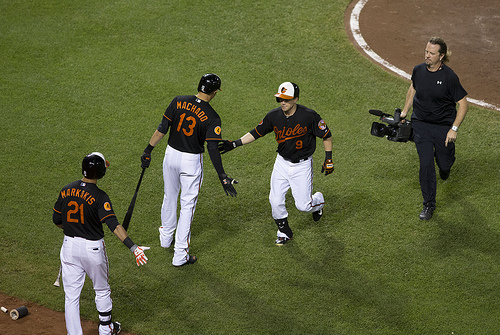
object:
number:
[177, 113, 196, 136]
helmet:
[197, 73, 222, 94]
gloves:
[206, 140, 238, 197]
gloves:
[320, 150, 334, 174]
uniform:
[52, 179, 118, 241]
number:
[294, 139, 303, 148]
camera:
[368, 108, 413, 142]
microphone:
[368, 109, 384, 116]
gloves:
[219, 138, 240, 154]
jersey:
[157, 95, 221, 154]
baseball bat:
[120, 169, 145, 231]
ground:
[318, 208, 379, 253]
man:
[140, 73, 240, 266]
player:
[217, 81, 334, 247]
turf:
[78, 51, 163, 97]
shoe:
[171, 255, 198, 268]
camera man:
[399, 38, 469, 219]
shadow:
[427, 190, 499, 257]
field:
[1, 1, 498, 333]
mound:
[384, 13, 494, 68]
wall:
[268, 153, 324, 219]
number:
[67, 200, 79, 224]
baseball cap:
[273, 80, 301, 100]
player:
[52, 152, 151, 314]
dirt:
[364, 49, 403, 98]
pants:
[159, 143, 205, 266]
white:
[83, 258, 128, 335]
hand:
[397, 109, 407, 122]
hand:
[141, 151, 152, 168]